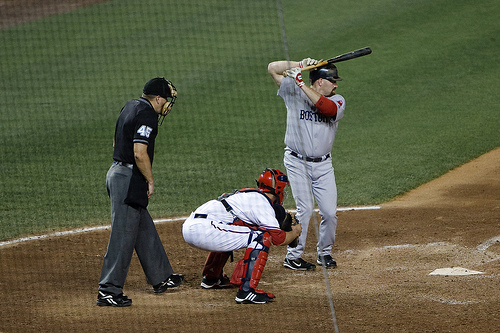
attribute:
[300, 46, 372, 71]
bat — black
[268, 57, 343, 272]
batter — ready, preparing, waiting, standing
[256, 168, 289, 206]
helmet — red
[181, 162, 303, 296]
catcher — croutched, squatting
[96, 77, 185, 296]
umpire — watching, stepping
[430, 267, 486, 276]
plate — white, diamond-shaped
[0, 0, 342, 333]
net — protective, up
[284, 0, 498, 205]
grass — green